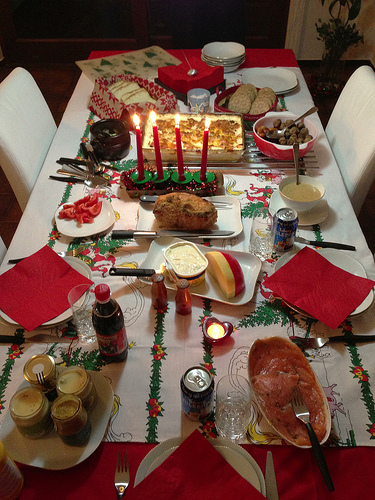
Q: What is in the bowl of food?
A: Fork.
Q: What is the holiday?
A: Christmas.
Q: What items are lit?
A: Candles.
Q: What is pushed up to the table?
A: Chair.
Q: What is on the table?
A: Tablecloth.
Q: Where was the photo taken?
A: Dining room.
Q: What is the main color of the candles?
A: Red.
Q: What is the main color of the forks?
A: Gray.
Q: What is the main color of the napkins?
A: Red.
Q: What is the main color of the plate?
A: White.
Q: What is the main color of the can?
A: Silver.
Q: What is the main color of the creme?
A: Yellow.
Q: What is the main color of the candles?
A: Yellow.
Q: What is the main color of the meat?
A: Brown.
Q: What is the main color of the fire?
A: Yellow.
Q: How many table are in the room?
A: 1.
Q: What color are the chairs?
A: White.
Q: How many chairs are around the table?
A: 2.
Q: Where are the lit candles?
A: Near the center of the table.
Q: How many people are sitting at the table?
A: 0.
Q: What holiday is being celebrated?
A: Christmas.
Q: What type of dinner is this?
A: Christmas dinner.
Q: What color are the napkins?
A: Red.